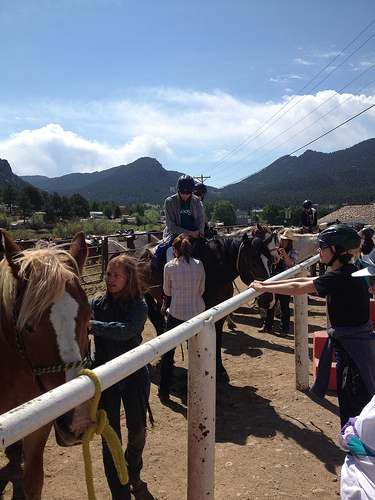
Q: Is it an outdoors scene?
A: Yes, it is outdoors.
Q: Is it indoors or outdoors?
A: It is outdoors.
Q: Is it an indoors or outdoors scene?
A: It is outdoors.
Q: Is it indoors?
A: No, it is outdoors.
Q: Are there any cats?
A: No, there are no cats.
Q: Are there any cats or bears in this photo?
A: No, there are no cats or bears.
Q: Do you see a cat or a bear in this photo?
A: No, there are no cats or bears.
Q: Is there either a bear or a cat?
A: No, there are no cats or bears.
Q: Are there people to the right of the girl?
A: Yes, there is a person to the right of the girl.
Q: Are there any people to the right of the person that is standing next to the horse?
A: Yes, there is a person to the right of the girl.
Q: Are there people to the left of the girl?
A: No, the person is to the right of the girl.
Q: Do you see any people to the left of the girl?
A: No, the person is to the right of the girl.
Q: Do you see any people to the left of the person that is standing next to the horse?
A: No, the person is to the right of the girl.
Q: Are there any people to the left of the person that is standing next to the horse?
A: No, the person is to the right of the girl.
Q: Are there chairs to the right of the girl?
A: No, there is a person to the right of the girl.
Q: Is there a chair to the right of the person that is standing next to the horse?
A: No, there is a person to the right of the girl.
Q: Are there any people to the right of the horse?
A: Yes, there is a person to the right of the horse.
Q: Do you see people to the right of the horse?
A: Yes, there is a person to the right of the horse.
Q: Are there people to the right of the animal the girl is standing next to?
A: Yes, there is a person to the right of the horse.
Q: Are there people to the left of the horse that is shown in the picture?
A: No, the person is to the right of the horse.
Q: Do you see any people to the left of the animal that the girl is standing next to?
A: No, the person is to the right of the horse.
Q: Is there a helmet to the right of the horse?
A: No, there is a person to the right of the horse.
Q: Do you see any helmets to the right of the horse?
A: No, there is a person to the right of the horse.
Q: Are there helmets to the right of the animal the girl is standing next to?
A: No, there is a person to the right of the horse.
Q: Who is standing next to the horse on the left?
A: The girl is standing next to the horse.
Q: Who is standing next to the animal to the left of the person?
A: The girl is standing next to the horse.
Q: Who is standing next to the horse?
A: The girl is standing next to the horse.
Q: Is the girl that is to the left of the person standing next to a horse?
A: Yes, the girl is standing next to a horse.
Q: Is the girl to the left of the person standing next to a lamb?
A: No, the girl is standing next to a horse.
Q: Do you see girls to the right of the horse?
A: Yes, there is a girl to the right of the horse.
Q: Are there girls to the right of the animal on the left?
A: Yes, there is a girl to the right of the horse.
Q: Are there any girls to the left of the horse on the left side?
A: No, the girl is to the right of the horse.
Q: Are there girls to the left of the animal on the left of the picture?
A: No, the girl is to the right of the horse.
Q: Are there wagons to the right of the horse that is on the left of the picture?
A: No, there is a girl to the right of the horse.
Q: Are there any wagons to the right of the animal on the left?
A: No, there is a girl to the right of the horse.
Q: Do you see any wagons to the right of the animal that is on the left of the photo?
A: No, there is a girl to the right of the horse.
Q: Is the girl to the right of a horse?
A: Yes, the girl is to the right of a horse.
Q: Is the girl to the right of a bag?
A: No, the girl is to the right of a horse.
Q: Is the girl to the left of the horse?
A: No, the girl is to the right of the horse.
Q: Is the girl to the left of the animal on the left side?
A: No, the girl is to the right of the horse.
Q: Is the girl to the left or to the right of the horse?
A: The girl is to the right of the horse.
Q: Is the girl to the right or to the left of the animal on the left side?
A: The girl is to the right of the horse.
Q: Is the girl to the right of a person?
A: No, the girl is to the left of a person.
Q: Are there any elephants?
A: No, there are no elephants.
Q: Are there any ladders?
A: No, there are no ladders.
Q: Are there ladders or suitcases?
A: No, there are no ladders or suitcases.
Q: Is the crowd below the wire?
A: Yes, the crowd is below the wire.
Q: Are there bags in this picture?
A: No, there are no bags.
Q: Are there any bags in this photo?
A: No, there are no bags.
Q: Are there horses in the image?
A: Yes, there is a horse.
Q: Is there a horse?
A: Yes, there is a horse.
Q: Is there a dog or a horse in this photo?
A: Yes, there is a horse.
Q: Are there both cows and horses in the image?
A: No, there is a horse but no cows.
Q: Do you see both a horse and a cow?
A: No, there is a horse but no cows.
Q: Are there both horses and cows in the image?
A: No, there is a horse but no cows.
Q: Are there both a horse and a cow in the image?
A: No, there is a horse but no cows.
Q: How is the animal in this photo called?
A: The animal is a horse.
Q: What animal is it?
A: The animal is a horse.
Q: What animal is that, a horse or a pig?
A: That is a horse.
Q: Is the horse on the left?
A: Yes, the horse is on the left of the image.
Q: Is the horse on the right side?
A: No, the horse is on the left of the image.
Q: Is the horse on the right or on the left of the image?
A: The horse is on the left of the image.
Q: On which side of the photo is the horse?
A: The horse is on the left of the image.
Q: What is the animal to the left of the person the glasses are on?
A: The animal is a horse.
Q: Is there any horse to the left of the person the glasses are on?
A: Yes, there is a horse to the left of the person.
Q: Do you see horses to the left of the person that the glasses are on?
A: Yes, there is a horse to the left of the person.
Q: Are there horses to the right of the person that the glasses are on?
A: No, the horse is to the left of the person.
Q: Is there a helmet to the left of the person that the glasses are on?
A: No, there is a horse to the left of the person.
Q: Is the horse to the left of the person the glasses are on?
A: Yes, the horse is to the left of the person.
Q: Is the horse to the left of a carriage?
A: No, the horse is to the left of the person.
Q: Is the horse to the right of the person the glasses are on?
A: No, the horse is to the left of the person.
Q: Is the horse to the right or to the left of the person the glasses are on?
A: The horse is to the left of the person.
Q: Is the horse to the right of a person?
A: No, the horse is to the left of a person.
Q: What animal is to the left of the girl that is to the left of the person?
A: The animal is a horse.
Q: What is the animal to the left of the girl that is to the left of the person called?
A: The animal is a horse.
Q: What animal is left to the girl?
A: The animal is a horse.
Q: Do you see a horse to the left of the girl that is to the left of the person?
A: Yes, there is a horse to the left of the girl.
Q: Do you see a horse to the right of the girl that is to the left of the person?
A: No, the horse is to the left of the girl.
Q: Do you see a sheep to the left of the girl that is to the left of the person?
A: No, there is a horse to the left of the girl.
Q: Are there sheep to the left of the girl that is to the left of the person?
A: No, there is a horse to the left of the girl.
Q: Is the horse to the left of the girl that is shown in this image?
A: Yes, the horse is to the left of the girl.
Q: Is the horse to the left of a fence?
A: No, the horse is to the left of the girl.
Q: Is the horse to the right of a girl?
A: No, the horse is to the left of a girl.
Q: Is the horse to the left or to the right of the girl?
A: The horse is to the left of the girl.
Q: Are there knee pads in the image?
A: No, there are no knee pads.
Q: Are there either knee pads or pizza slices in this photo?
A: No, there are no knee pads or pizza slices.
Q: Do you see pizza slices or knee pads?
A: No, there are no knee pads or pizza slices.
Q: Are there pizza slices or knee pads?
A: No, there are no knee pads or pizza slices.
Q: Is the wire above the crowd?
A: Yes, the wire is above the crowd.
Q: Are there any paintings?
A: No, there are no paintings.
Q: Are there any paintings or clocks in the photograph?
A: No, there are no paintings or clocks.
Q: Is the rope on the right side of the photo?
A: No, the rope is on the left of the image.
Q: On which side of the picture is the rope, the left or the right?
A: The rope is on the left of the image.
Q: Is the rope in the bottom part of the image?
A: Yes, the rope is in the bottom of the image.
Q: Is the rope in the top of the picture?
A: No, the rope is in the bottom of the image.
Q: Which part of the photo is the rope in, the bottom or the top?
A: The rope is in the bottom of the image.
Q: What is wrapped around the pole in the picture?
A: The rope is wrapped around the pole.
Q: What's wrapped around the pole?
A: The rope is wrapped around the pole.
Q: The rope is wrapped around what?
A: The rope is wrapped around the pole.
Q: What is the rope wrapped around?
A: The rope is wrapped around the pole.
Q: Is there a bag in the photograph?
A: No, there are no bags.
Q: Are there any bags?
A: No, there are no bags.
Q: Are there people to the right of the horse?
A: Yes, there is a person to the right of the horse.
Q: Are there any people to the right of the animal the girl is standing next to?
A: Yes, there is a person to the right of the horse.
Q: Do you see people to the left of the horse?
A: No, the person is to the right of the horse.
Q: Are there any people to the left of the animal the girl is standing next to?
A: No, the person is to the right of the horse.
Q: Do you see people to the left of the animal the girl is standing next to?
A: No, the person is to the right of the horse.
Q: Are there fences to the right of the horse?
A: No, there is a person to the right of the horse.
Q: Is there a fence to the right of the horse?
A: No, there is a person to the right of the horse.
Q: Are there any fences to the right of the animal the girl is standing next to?
A: No, there is a person to the right of the horse.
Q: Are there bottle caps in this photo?
A: No, there are no bottle caps.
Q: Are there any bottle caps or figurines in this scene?
A: No, there are no bottle caps or figurines.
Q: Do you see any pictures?
A: No, there are no pictures.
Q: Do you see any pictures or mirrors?
A: No, there are no pictures or mirrors.